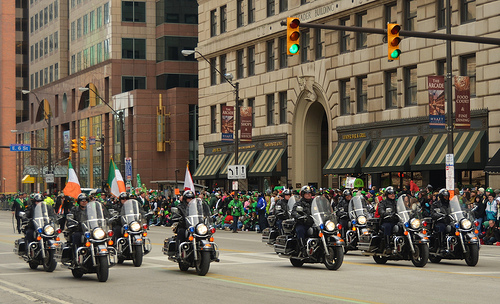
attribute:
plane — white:
[365, 181, 437, 272]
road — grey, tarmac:
[1, 205, 498, 302]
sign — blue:
[8, 142, 33, 153]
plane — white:
[153, 94, 169, 151]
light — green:
[278, 18, 304, 68]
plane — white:
[458, 71, 484, 246]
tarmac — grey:
[342, 251, 470, 288]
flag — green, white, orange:
[60, 158, 80, 202]